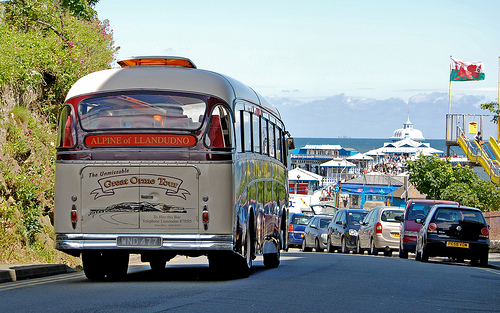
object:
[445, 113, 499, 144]
rail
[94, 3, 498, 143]
sky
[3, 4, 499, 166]
distance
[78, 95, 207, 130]
window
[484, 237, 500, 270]
sidewalk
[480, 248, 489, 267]
part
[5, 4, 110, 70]
trees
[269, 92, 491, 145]
mountain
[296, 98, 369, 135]
part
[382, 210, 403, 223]
part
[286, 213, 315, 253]
car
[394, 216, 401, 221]
side mirror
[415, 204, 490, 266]
car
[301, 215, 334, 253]
car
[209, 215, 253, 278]
tire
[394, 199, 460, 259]
truck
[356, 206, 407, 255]
car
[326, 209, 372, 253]
car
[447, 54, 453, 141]
pole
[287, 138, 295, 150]
mirror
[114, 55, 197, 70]
vent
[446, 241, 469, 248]
license plate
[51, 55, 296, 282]
bus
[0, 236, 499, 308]
road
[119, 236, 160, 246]
license plate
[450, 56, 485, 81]
flag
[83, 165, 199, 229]
advertisement